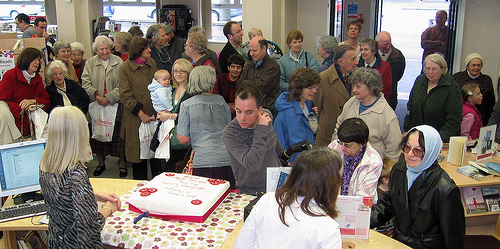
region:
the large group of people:
[0, 0, 497, 247]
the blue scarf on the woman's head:
[399, 123, 443, 188]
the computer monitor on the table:
[0, 137, 48, 197]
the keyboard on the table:
[0, 200, 46, 222]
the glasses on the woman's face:
[400, 141, 424, 157]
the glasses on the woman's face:
[172, 68, 184, 75]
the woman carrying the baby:
[149, 56, 193, 174]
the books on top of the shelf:
[440, 124, 499, 181]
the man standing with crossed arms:
[420, 8, 450, 63]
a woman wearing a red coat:
[13, 43, 45, 104]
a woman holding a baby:
[150, 67, 188, 119]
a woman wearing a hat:
[463, 48, 486, 82]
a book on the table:
[441, 123, 473, 174]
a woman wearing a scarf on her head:
[406, 121, 440, 185]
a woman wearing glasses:
[45, 64, 68, 90]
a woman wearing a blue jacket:
[280, 66, 313, 140]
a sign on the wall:
[343, 5, 365, 26]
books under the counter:
[13, 229, 51, 247]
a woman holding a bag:
[86, 82, 134, 160]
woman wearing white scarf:
[429, 131, 439, 152]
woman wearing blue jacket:
[281, 114, 301, 136]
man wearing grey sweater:
[236, 138, 243, 151]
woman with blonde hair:
[176, 63, 189, 68]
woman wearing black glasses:
[172, 67, 188, 77]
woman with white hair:
[63, 119, 78, 142]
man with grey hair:
[96, 37, 108, 45]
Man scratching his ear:
[219, 80, 289, 191]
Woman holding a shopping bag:
[78, 33, 130, 179]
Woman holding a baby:
[149, 57, 191, 172]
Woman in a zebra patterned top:
[37, 102, 121, 247]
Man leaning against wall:
[417, 4, 456, 81]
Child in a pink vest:
[458, 79, 485, 140]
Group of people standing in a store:
[2, 19, 499, 185]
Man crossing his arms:
[235, 36, 280, 101]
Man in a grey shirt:
[219, 83, 286, 197]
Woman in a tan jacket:
[78, 34, 130, 174]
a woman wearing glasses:
[400, 137, 423, 166]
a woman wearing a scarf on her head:
[403, 118, 433, 177]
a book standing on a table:
[443, 123, 479, 178]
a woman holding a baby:
[152, 59, 191, 123]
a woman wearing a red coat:
[4, 50, 50, 110]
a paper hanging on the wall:
[341, 2, 364, 21]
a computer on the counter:
[4, 136, 39, 216]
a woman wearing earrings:
[353, 130, 371, 167]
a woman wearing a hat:
[464, 43, 484, 82]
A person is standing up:
[182, 60, 236, 183]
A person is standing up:
[159, 59, 194, 172]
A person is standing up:
[111, 30, 170, 177]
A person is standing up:
[86, 33, 137, 133]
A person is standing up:
[46, 55, 88, 120]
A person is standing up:
[51, 42, 78, 80]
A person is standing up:
[66, 42, 93, 78]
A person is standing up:
[267, 59, 327, 152]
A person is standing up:
[319, 65, 407, 173]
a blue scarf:
[398, 125, 443, 187]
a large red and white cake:
[124, 170, 243, 217]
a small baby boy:
[145, 70, 176, 115]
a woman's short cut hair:
[334, 118, 373, 151]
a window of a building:
[101, 0, 154, 31]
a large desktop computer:
[0, 137, 58, 220]